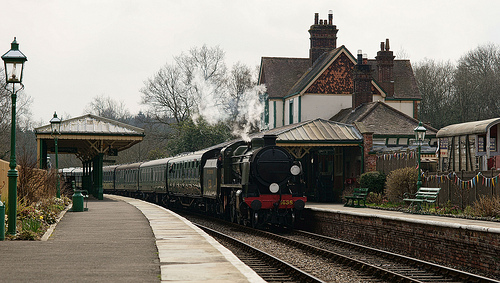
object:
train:
[46, 143, 304, 232]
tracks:
[199, 207, 491, 282]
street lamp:
[3, 35, 25, 239]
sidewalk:
[4, 192, 199, 282]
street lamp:
[47, 108, 66, 211]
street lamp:
[407, 119, 432, 209]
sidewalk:
[333, 202, 498, 234]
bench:
[402, 187, 450, 215]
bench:
[342, 188, 368, 208]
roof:
[252, 50, 422, 91]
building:
[255, 8, 424, 188]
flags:
[421, 175, 499, 191]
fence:
[377, 156, 499, 214]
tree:
[139, 41, 254, 151]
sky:
[5, 1, 494, 62]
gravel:
[308, 255, 327, 281]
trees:
[448, 39, 499, 124]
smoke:
[186, 69, 267, 136]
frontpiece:
[249, 194, 306, 208]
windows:
[194, 167, 200, 178]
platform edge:
[217, 250, 254, 282]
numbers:
[280, 199, 294, 205]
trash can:
[72, 192, 83, 212]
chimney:
[308, 5, 335, 76]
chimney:
[375, 37, 399, 103]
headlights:
[269, 182, 280, 193]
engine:
[224, 132, 293, 192]